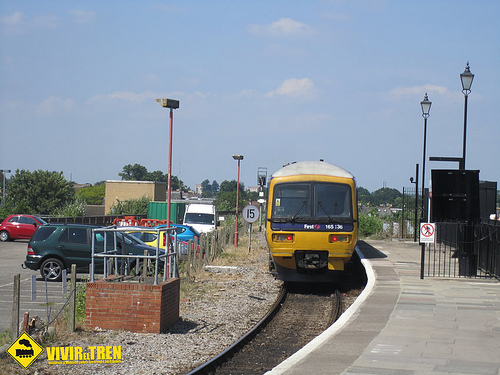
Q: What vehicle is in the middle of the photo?
A: Train.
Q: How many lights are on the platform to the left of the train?
A: Two.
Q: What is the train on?
A: Tracks.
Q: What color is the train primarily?
A: Yellow.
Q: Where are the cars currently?
A: Parking lot.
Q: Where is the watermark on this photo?
A: Bottom left.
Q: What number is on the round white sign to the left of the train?
A: Fifteen.